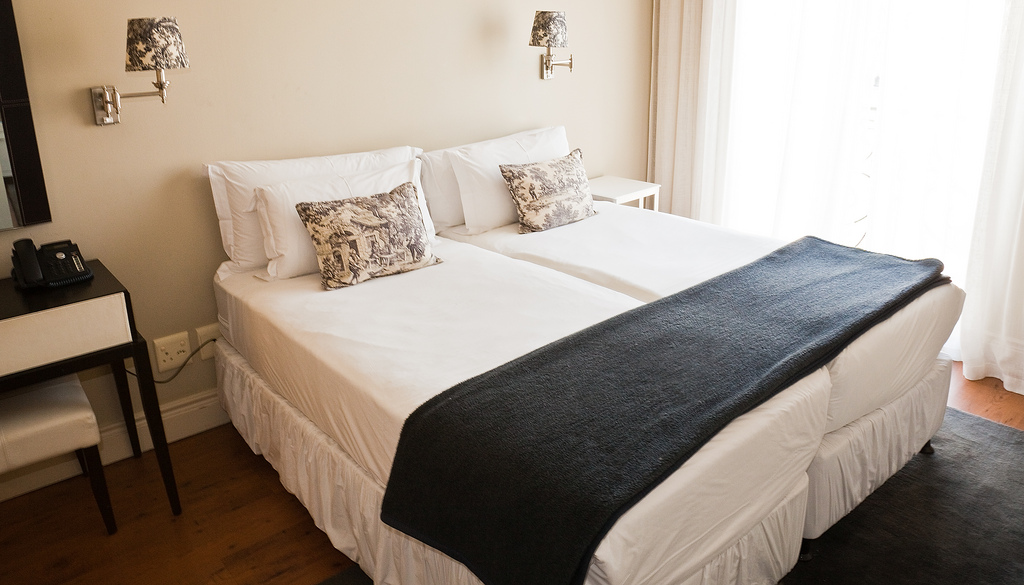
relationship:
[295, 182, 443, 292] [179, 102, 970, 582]
pillow on bed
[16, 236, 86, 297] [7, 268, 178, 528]
telephone on desk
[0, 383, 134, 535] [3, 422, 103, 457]
bench has edge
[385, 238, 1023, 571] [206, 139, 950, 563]
blanket on bed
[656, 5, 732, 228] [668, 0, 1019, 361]
curtains hanging in window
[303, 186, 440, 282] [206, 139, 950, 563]
pillow on bed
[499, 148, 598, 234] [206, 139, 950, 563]
pillow on bed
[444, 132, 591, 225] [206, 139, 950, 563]
pillow on bed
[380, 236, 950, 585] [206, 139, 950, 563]
blanket on bed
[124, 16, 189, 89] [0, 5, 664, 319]
lamp on wall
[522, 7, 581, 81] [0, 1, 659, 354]
lamp on wall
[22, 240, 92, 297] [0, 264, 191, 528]
phone on desk